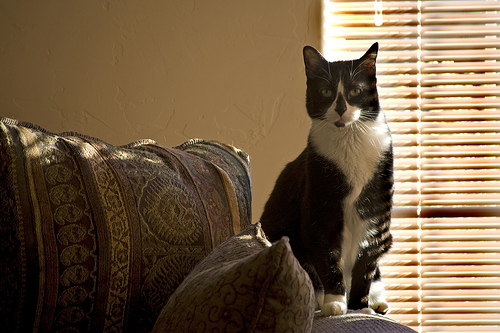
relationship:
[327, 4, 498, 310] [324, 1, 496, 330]
miniblinds covers window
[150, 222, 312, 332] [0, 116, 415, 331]
pillow on couch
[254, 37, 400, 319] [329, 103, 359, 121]
cat has nose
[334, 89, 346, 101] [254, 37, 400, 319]
spot on cat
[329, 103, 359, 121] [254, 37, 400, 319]
nose on cat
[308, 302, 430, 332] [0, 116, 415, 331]
arm on couch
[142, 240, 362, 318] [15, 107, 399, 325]
pillow on couch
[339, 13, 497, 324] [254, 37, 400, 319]
window behind cat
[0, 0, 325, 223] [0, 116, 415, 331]
wall behind couch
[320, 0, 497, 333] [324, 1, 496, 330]
miniblinds on window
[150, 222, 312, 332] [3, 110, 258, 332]
pillow on sofa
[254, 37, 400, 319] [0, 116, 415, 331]
cat on couch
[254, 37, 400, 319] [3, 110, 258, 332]
cat on sofa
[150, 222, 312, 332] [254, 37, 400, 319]
pillow near cat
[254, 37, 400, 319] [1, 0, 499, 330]
cat in house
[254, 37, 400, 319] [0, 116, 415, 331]
cat sitting on couch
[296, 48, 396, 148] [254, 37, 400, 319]
face on cat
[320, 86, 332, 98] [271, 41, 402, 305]
eye on cat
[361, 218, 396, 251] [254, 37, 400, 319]
sunlight on cat